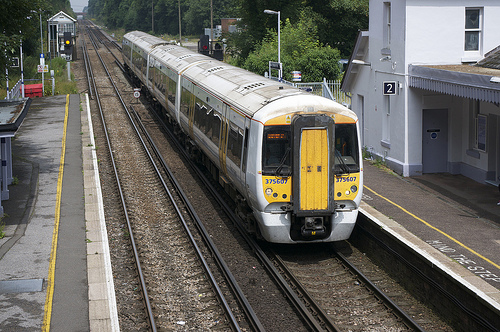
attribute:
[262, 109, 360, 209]
front — painted, yellow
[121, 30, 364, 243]
train — steel, metal, white, painted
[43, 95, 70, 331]
line — yellow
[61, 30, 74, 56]
train signal — yellow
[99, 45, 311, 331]
gravel — dark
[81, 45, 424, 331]
tracks — metal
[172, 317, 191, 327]
trash — white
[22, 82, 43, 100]
thingamajiggy — red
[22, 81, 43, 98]
object — red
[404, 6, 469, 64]
wall surface — bright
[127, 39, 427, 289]
train — incoming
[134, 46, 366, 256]
train — incoming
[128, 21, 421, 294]
train — incoming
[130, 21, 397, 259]
train — incoming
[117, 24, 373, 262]
train — incoming